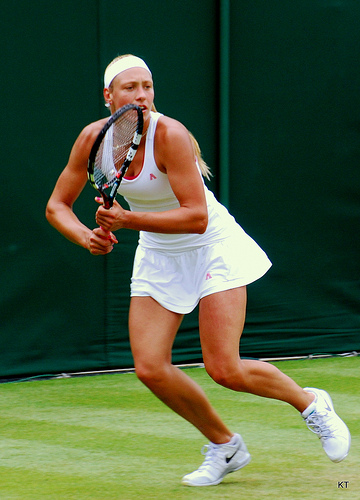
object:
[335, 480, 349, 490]
logo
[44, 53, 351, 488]
woman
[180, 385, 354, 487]
shoes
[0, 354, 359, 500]
court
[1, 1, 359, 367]
wall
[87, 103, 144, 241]
racket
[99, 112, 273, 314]
outfit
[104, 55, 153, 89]
band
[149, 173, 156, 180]
logo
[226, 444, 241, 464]
logo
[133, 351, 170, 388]
knees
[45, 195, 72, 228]
elbows